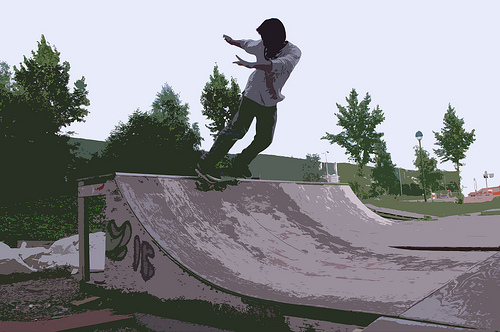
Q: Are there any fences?
A: No, there are no fences.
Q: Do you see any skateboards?
A: Yes, there is a skateboard.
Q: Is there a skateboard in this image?
A: Yes, there is a skateboard.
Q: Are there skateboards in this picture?
A: Yes, there is a skateboard.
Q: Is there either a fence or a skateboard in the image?
A: Yes, there is a skateboard.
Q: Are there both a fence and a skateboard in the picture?
A: No, there is a skateboard but no fences.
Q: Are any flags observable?
A: No, there are no flags.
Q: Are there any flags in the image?
A: No, there are no flags.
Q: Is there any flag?
A: No, there are no flags.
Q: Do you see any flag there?
A: No, there are no flags.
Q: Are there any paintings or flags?
A: No, there are no flags or paintings.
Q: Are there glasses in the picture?
A: No, there are no glasses.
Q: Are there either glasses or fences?
A: No, there are no glasses or fences.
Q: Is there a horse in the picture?
A: Yes, there is a horse.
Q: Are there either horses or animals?
A: Yes, there is a horse.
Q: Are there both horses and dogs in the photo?
A: No, there is a horse but no dogs.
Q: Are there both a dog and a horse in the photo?
A: No, there is a horse but no dogs.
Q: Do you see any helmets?
A: No, there are no helmets.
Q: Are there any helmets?
A: No, there are no helmets.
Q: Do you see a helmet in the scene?
A: No, there are no helmets.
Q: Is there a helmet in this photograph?
A: No, there are no helmets.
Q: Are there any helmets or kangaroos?
A: No, there are no helmets or kangaroos.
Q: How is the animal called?
A: The animal is a horse.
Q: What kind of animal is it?
A: The animal is a horse.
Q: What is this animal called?
A: That is a horse.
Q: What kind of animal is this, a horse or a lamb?
A: That is a horse.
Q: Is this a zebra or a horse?
A: This is a horse.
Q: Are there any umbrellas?
A: No, there are no umbrellas.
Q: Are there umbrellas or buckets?
A: No, there are no umbrellas or buckets.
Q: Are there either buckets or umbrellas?
A: No, there are no umbrellas or buckets.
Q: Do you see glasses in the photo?
A: No, there are no glasses.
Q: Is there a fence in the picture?
A: No, there are no fences.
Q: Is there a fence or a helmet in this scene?
A: No, there are no fences or helmets.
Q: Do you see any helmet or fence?
A: No, there are no fences or helmets.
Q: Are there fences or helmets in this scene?
A: No, there are no fences or helmets.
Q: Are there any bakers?
A: No, there are no bakers.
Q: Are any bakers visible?
A: No, there are no bakers.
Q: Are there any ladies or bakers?
A: No, there are no bakers or ladies.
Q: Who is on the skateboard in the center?
A: The man is on the skateboard.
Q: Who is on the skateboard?
A: The man is on the skateboard.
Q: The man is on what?
A: The man is on the skateboard.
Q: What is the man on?
A: The man is on the skateboard.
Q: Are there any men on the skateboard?
A: Yes, there is a man on the skateboard.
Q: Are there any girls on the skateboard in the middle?
A: No, there is a man on the skateboard.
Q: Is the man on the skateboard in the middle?
A: Yes, the man is on the skateboard.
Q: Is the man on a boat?
A: No, the man is on the skateboard.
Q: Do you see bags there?
A: No, there are no bags.